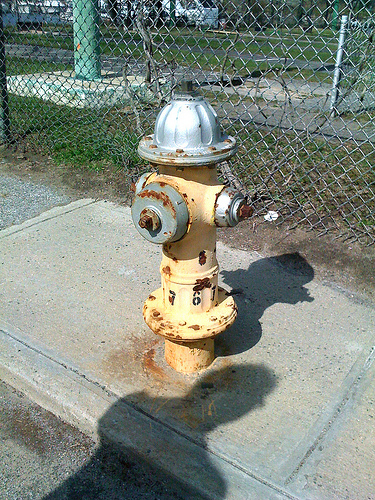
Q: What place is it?
A: It is a sidewalk.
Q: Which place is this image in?
A: It is at the sidewalk.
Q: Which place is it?
A: It is a sidewalk.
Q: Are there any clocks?
A: No, there are no clocks.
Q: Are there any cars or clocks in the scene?
A: No, there are no clocks or cars.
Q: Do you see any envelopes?
A: No, there are no envelopes.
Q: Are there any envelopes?
A: No, there are no envelopes.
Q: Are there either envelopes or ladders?
A: No, there are no envelopes or ladders.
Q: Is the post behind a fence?
A: Yes, the post is behind a fence.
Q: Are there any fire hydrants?
A: Yes, there is a fire hydrant.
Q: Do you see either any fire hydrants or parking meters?
A: Yes, there is a fire hydrant.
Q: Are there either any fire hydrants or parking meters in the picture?
A: Yes, there is a fire hydrant.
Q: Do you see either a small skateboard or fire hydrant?
A: Yes, there is a small fire hydrant.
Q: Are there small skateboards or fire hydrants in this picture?
A: Yes, there is a small fire hydrant.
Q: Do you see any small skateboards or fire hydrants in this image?
A: Yes, there is a small fire hydrant.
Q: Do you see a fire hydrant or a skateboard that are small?
A: Yes, the fire hydrant is small.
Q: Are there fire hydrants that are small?
A: Yes, there is a small fire hydrant.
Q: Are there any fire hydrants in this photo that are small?
A: Yes, there is a fire hydrant that is small.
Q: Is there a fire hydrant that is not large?
A: Yes, there is a small fire hydrant.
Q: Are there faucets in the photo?
A: No, there are no faucets.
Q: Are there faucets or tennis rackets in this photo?
A: No, there are no faucets or tennis rackets.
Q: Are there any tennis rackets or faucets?
A: No, there are no faucets or tennis rackets.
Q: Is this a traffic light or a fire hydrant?
A: This is a fire hydrant.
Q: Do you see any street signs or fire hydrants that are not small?
A: No, there is a fire hydrant but it is small.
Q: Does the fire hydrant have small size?
A: Yes, the fire hydrant is small.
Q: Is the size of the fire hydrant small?
A: Yes, the fire hydrant is small.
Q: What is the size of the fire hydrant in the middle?
A: The fire hydrant is small.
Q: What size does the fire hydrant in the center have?
A: The fire hydrant has small size.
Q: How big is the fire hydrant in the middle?
A: The fire hydrant is small.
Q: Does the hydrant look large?
A: No, the hydrant is small.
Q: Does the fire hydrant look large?
A: No, the fire hydrant is small.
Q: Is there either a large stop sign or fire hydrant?
A: No, there is a fire hydrant but it is small.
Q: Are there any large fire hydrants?
A: No, there is a fire hydrant but it is small.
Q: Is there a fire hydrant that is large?
A: No, there is a fire hydrant but it is small.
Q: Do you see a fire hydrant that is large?
A: No, there is a fire hydrant but it is small.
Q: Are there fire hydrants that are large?
A: No, there is a fire hydrant but it is small.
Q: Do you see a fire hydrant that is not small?
A: No, there is a fire hydrant but it is small.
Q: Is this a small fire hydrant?
A: Yes, this is a small fire hydrant.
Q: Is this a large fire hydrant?
A: No, this is a small fire hydrant.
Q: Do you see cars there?
A: No, there are no cars.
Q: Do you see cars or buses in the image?
A: No, there are no cars or buses.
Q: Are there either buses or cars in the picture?
A: No, there are no cars or buses.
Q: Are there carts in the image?
A: No, there are no carts.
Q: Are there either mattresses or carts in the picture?
A: No, there are no carts or mattresses.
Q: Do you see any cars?
A: No, there are no cars.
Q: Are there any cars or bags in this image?
A: No, there are no cars or bags.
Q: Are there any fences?
A: Yes, there is a fence.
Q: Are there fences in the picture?
A: Yes, there is a fence.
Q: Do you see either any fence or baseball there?
A: Yes, there is a fence.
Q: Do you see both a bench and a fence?
A: No, there is a fence but no benches.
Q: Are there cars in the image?
A: No, there are no cars.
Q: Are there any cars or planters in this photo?
A: No, there are no cars or planters.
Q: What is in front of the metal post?
A: The fence is in front of the post.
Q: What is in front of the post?
A: The fence is in front of the post.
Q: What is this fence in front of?
A: The fence is in front of the post.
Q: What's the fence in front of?
A: The fence is in front of the post.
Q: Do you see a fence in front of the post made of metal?
A: Yes, there is a fence in front of the post.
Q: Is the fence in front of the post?
A: Yes, the fence is in front of the post.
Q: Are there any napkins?
A: No, there are no napkins.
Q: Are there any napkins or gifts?
A: No, there are no napkins or gifts.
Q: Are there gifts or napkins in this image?
A: No, there are no napkins or gifts.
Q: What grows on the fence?
A: The vine grows on the fence.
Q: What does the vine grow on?
A: The vine grows on the fence.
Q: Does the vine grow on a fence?
A: Yes, the vine grows on a fence.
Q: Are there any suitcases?
A: No, there are no suitcases.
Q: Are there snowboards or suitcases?
A: No, there are no suitcases or snowboards.